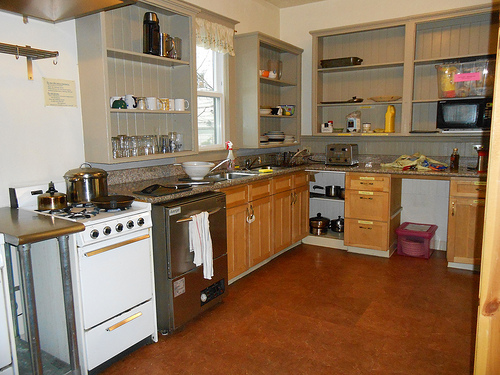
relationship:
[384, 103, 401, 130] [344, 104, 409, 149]
jug on shelf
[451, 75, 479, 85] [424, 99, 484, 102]
label on container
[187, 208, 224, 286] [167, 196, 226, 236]
towel on rack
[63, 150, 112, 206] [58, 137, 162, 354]
cooker on stove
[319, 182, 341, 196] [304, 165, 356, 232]
cooker in cabinet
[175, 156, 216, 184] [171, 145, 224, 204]
bowl on counter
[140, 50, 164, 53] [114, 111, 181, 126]
thermos on shelf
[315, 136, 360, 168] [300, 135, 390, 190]
toaster on cabinet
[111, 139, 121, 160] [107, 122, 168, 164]
glass on shelf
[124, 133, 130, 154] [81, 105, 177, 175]
glass on shelf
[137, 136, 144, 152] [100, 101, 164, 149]
glass on shelf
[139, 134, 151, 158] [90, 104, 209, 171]
glass on shelf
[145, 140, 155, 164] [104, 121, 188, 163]
glass on shelf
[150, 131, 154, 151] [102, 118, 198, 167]
glass on shelf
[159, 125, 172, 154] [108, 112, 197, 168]
glass on shelf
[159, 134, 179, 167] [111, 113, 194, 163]
glass on shelf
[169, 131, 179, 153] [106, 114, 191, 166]
glass on shelf